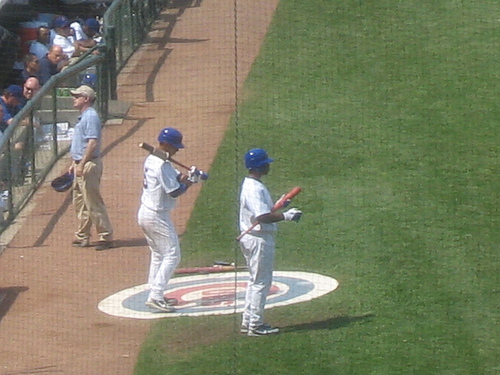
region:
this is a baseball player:
[212, 128, 328, 357]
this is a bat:
[228, 168, 311, 253]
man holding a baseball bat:
[128, 108, 220, 316]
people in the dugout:
[8, 3, 139, 223]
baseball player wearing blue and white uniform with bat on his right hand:
[134, 130, 201, 315]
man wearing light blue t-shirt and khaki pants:
[70, 83, 114, 251]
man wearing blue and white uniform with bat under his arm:
[237, 145, 304, 336]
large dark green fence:
[0, 0, 159, 231]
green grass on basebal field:
[131, 0, 495, 372]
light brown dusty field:
[0, 0, 277, 373]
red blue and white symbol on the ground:
[99, 263, 336, 325]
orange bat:
[234, 185, 301, 246]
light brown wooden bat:
[136, 140, 207, 180]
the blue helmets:
[155, 122, 271, 173]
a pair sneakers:
[146, 294, 281, 337]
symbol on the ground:
[94, 261, 339, 322]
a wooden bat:
[136, 138, 305, 240]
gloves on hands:
[186, 161, 303, 228]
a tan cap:
[68, 81, 95, 101]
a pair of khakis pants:
[68, 156, 113, 250]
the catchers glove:
[50, 168, 75, 194]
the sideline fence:
[1, 1, 173, 233]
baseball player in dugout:
[1, 83, 26, 186]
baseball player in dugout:
[15, 75, 41, 161]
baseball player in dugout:
[15, 53, 40, 98]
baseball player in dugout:
[35, 45, 69, 84]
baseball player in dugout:
[30, 25, 51, 63]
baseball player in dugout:
[51, 13, 98, 64]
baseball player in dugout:
[73, 12, 105, 51]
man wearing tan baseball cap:
[54, 82, 114, 250]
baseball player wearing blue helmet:
[138, 125, 204, 310]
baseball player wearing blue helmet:
[234, 145, 302, 336]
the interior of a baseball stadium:
[0, 0, 498, 374]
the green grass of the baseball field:
[132, 0, 498, 374]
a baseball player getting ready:
[235, 148, 302, 335]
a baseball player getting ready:
[137, 127, 207, 312]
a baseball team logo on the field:
[97, 270, 339, 317]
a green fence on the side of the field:
[0, 0, 169, 236]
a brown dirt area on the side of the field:
[0, 0, 279, 374]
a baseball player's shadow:
[271, 312, 375, 334]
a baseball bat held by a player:
[235, 185, 302, 242]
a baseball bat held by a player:
[137, 141, 192, 170]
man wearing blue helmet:
[240, 145, 316, 353]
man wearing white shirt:
[233, 133, 311, 340]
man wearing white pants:
[238, 143, 306, 349]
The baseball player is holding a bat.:
[138, 138, 209, 173]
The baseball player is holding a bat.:
[236, 185, 300, 237]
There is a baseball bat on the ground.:
[171, 253, 245, 280]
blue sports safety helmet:
[242, 142, 278, 174]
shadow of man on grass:
[270, 307, 385, 340]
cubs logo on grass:
[94, 265, 339, 326]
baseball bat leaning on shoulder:
[131, 140, 219, 184]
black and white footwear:
[233, 314, 290, 341]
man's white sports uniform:
[230, 174, 285, 330]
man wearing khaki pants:
[45, 80, 122, 260]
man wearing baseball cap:
[40, 83, 117, 255]